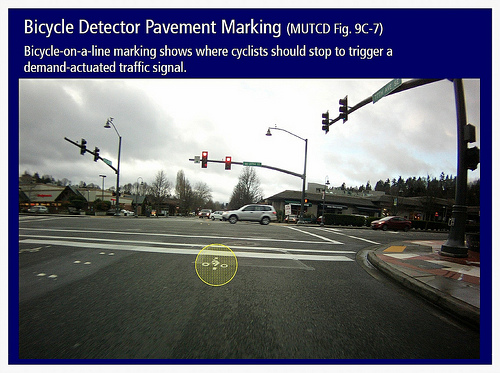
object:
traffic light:
[321, 107, 331, 137]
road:
[19, 213, 480, 358]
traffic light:
[80, 136, 89, 155]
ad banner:
[19, 8, 481, 79]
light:
[199, 150, 209, 169]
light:
[223, 156, 233, 170]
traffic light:
[336, 94, 351, 126]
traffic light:
[92, 146, 101, 162]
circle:
[193, 242, 237, 286]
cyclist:
[197, 255, 231, 272]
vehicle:
[218, 201, 279, 226]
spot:
[382, 243, 408, 254]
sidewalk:
[367, 236, 481, 319]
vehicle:
[368, 213, 419, 232]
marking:
[19, 236, 354, 263]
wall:
[280, 199, 484, 228]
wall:
[23, 188, 82, 207]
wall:
[143, 204, 180, 214]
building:
[253, 188, 481, 232]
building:
[19, 183, 136, 210]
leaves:
[377, 179, 395, 195]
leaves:
[430, 175, 450, 191]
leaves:
[425, 176, 451, 195]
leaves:
[371, 176, 390, 192]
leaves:
[29, 174, 42, 185]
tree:
[427, 174, 440, 192]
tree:
[407, 173, 415, 191]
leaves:
[184, 184, 193, 211]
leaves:
[405, 177, 424, 193]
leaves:
[387, 183, 408, 195]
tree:
[42, 173, 49, 183]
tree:
[438, 171, 447, 192]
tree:
[373, 176, 386, 195]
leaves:
[229, 184, 252, 204]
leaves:
[178, 179, 192, 211]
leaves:
[433, 174, 455, 194]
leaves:
[395, 176, 417, 191]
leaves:
[43, 172, 51, 184]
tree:
[226, 165, 262, 208]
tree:
[425, 174, 431, 196]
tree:
[406, 175, 414, 191]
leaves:
[338, 185, 354, 194]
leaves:
[402, 170, 425, 192]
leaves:
[437, 169, 457, 195]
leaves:
[29, 171, 51, 188]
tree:
[336, 179, 353, 193]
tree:
[397, 176, 405, 194]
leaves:
[360, 177, 388, 191]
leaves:
[387, 176, 404, 192]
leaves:
[406, 171, 426, 194]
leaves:
[31, 171, 55, 185]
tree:
[364, 178, 373, 191]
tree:
[423, 173, 434, 191]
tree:
[443, 172, 450, 198]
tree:
[31, 169, 42, 190]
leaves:
[182, 177, 203, 203]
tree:
[175, 170, 196, 213]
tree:
[165, 202, 181, 216]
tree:
[419, 192, 438, 222]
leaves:
[413, 168, 433, 190]